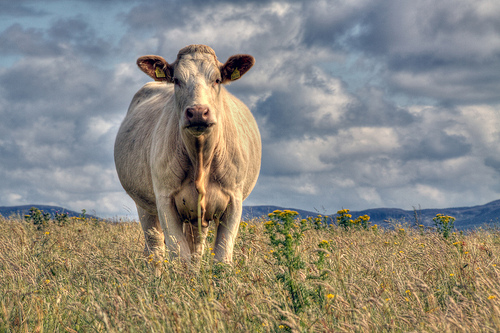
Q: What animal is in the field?
A: A cow.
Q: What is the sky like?
A: Grey and cloudy.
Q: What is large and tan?
A: A cow.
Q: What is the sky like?
A: Gloomy.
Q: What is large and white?
A: A cow.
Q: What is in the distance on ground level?
A: Mountains.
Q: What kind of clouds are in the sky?
A: White clouds.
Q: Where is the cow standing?
A: In tall grass.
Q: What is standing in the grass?
A: A white cow.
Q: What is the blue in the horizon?
A: Mountains.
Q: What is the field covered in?
A: Dry brush.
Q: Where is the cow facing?
A: Straight ahead.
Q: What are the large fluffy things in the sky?
A: Clouds.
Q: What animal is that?
A: Cow.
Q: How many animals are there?
A: One.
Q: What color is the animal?
A: Cream.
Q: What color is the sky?
A: Gray.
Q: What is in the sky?
A: Clouds.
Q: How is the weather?
A: Sunny.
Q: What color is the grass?
A: Yellow.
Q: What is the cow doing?
A: Standing.